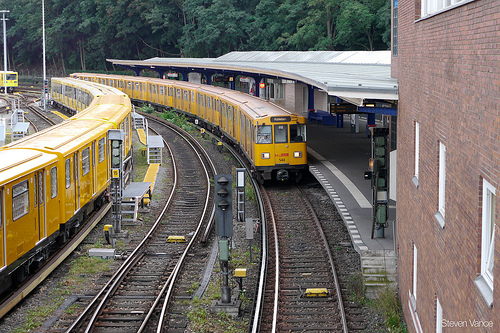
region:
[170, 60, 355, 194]
Yellow train at train station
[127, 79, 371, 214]
Yellow train next to train tracks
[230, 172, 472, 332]
train platform next to brick building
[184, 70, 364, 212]
Yellow train stopped at train platform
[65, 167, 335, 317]
switching station on train tracks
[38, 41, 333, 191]
Yellow trains passing each other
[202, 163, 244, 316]
Black train signal with green box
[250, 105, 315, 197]
Front windows of yellow train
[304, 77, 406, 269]
White caution markings on train platform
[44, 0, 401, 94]
green trees behind train platform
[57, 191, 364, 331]
railroad tracks on the ground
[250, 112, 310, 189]
front of the yellow train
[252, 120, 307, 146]
windshield of the train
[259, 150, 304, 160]
front lights of the train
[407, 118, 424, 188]
a window on the wall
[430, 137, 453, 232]
a window of the building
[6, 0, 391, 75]
green trees in the background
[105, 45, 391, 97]
a roof a building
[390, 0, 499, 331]
a brick wall of the building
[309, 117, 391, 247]
a platform of the train station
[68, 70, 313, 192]
train on the tracks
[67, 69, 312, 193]
a yellow train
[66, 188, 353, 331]
rail tracks on the ground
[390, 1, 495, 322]
a brick wall of a building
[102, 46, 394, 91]
a roof of the waiting area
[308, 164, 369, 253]
broken white lines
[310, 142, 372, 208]
solid white line painted on the ground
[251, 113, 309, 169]
a front of the train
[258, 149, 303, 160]
lights in front of the train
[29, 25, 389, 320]
passenger train in a city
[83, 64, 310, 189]
the train is turning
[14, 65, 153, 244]
this train is curved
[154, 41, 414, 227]
the train depot for the passengers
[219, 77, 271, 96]
lights on the train station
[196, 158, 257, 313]
lights on the tracks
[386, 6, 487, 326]
a red brick building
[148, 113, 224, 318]
train tracks in the train yard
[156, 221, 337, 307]
yellow stop plates for the train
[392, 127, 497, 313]
windows on the building